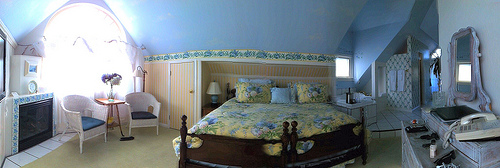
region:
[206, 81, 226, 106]
A lamp on the end table.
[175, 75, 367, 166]
A flower print bed.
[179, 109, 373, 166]
The brown wooden bed frame.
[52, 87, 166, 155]
A pair of white chairs.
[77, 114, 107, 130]
A blue seat cushion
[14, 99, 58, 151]
A black fire place.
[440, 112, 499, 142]
A phone on the dresser.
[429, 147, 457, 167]
Sun glasses on the dresser.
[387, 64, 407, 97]
Towels on the wall.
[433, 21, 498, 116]
A mirror on the dresser.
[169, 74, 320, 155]
the bed is yellow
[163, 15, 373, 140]
the bed is yellow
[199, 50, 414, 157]
the bed is yellow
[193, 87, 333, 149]
the bed sheet is yellow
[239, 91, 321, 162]
the bed sheet is yellow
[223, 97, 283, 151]
the bed sheet is yellow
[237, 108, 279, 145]
the bed sheet is yellow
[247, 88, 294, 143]
the bed sheet is yellow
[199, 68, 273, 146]
the bed sheet is yellow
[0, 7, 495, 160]
bedroom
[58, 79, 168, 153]
two wicker chairs in front of a window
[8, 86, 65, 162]
a fireplace with white trim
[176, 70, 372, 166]
a neatly-made bed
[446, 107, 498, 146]
white land-line telephone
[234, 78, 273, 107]
pillow matching the bedspread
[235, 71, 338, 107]
pillows on the bed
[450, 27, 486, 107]
mirror over the dresser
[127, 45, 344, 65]
wallpaper border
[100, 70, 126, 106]
flowers in a vase on the table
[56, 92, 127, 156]
the chair is white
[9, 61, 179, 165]
the chair is white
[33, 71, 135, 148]
the chair is white